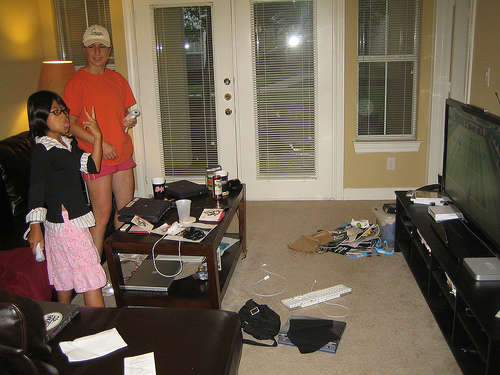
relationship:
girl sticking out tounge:
[23, 94, 120, 307] [66, 125, 70, 128]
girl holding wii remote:
[23, 94, 120, 307] [32, 244, 46, 259]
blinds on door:
[233, 3, 339, 202] [253, 4, 315, 178]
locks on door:
[223, 77, 232, 86] [129, 5, 236, 186]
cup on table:
[175, 196, 191, 227] [140, 178, 244, 305]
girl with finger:
[23, 94, 120, 307] [78, 109, 93, 119]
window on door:
[151, 10, 220, 176] [253, 4, 315, 178]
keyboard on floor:
[283, 276, 351, 300] [244, 202, 440, 346]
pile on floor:
[305, 222, 391, 249] [244, 202, 440, 346]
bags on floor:
[236, 298, 284, 339] [244, 202, 440, 346]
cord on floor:
[256, 262, 288, 296] [244, 202, 440, 346]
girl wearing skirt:
[23, 94, 120, 307] [38, 219, 111, 293]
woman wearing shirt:
[61, 27, 144, 246] [66, 74, 138, 164]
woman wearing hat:
[61, 27, 144, 246] [81, 28, 112, 43]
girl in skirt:
[23, 94, 120, 307] [38, 219, 111, 293]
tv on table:
[443, 97, 499, 250] [140, 178, 244, 305]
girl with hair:
[23, 94, 120, 307] [23, 92, 67, 131]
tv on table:
[443, 97, 499, 250] [396, 192, 499, 344]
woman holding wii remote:
[61, 27, 144, 246] [126, 111, 139, 128]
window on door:
[151, 10, 220, 176] [129, 5, 236, 186]